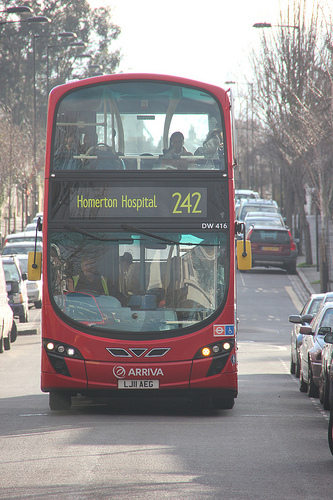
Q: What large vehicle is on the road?
A: A bus.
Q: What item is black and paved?
A: The road.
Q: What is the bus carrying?
A: Passengers.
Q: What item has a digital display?
A: A bus.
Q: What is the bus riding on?
A: The road.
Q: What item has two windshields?
A: A bus.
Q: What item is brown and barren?
A: A tree.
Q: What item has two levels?
A: A bus.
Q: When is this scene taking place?
A: Daytime.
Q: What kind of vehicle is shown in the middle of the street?
A: Bus.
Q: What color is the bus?
A: Red.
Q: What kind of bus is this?
A: Double decker bus.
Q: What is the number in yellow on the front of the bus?
A: 242.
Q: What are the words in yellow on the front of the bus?
A: Homerton hospital.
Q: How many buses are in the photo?
A: One.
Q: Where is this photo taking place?
A: On the street.